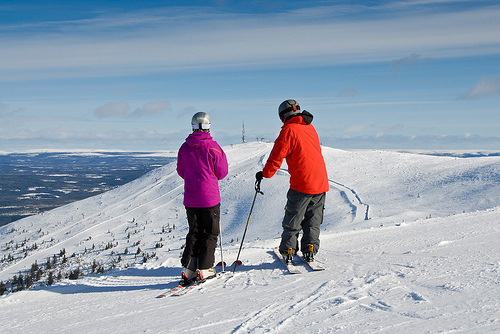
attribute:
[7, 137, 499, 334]
snow — white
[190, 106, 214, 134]
helmet — silver, shiney, gray, white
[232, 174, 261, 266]
stick — long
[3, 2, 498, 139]
sky — beautiful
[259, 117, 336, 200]
jacket — red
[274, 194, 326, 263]
pants — gray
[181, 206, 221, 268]
pants — black, grey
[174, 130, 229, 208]
jacket — pink, purple, red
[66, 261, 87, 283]
tree — down hill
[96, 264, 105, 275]
evergreen — down hill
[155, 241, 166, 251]
tree — down hill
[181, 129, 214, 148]
hoodie — pink